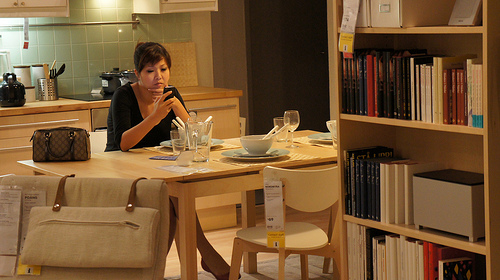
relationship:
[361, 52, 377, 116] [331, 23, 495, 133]
book in shelf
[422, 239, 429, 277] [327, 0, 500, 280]
book on bookshelf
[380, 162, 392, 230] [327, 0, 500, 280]
book in a bookshelf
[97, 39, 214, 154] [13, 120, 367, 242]
woman at table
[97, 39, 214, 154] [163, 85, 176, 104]
woman on cell phone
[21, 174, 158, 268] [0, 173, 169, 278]
organizer hanging off chair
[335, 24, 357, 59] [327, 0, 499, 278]
tag hanging on bookshelf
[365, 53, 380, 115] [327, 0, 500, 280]
red books on bookshelf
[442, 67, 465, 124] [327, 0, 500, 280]
red books on bookshelf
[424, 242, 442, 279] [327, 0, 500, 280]
red books on bookshelf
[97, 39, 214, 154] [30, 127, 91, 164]
woman with bag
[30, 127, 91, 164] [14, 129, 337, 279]
bag on table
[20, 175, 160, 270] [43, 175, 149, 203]
bag with handles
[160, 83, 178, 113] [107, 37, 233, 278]
cell phone being held by woman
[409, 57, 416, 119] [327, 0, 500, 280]
book on bookshelf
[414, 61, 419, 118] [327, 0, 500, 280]
book on bookshelf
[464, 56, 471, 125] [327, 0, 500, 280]
book on bookshelf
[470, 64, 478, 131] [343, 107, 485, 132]
book on shelf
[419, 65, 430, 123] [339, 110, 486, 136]
white book on shelf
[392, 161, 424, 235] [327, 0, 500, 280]
book in bookshelf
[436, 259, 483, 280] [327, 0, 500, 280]
book in a bookshelf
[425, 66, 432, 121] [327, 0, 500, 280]
book on bookshelf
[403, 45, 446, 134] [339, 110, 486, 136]
book on shelf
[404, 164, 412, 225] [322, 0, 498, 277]
book on tan shelf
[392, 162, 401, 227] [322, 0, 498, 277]
white book on tan shelf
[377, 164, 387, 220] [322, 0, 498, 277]
white book on tan shelf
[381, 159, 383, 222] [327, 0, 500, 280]
book on bookshelf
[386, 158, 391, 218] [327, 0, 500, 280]
book on bookshelf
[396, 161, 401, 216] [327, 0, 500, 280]
book on bookshelf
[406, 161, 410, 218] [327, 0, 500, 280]
book on bookshelf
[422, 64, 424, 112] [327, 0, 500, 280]
book on bookshelf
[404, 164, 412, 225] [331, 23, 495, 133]
book on shelf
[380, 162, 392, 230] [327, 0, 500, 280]
book in bookshelf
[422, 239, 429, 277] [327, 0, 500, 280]
book in bookshelf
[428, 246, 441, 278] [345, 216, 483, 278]
book in a shelf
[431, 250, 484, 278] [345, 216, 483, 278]
book in shelf